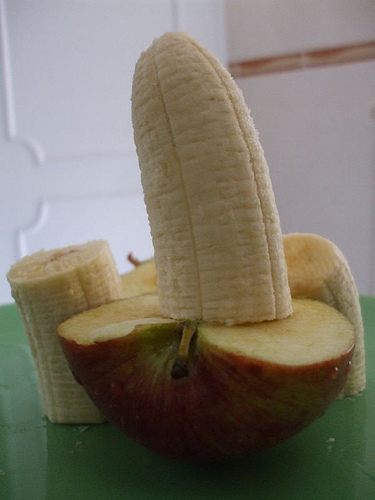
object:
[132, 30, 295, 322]
piece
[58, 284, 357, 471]
apple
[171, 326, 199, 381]
stem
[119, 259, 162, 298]
apple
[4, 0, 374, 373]
background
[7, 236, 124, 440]
piece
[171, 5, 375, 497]
left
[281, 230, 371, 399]
piece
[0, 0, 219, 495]
right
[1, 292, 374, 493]
counter top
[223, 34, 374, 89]
decoration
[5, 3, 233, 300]
wall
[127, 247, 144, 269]
stem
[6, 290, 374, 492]
counter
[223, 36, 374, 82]
sign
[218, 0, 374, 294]
wall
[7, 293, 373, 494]
table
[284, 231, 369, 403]
bananas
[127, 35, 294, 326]
bananas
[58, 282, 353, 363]
flesh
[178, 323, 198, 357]
ring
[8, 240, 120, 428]
banana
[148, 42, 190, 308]
line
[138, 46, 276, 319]
side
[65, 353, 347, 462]
skin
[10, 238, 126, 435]
section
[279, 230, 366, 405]
section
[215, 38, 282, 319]
lines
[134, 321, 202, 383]
color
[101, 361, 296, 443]
coloring